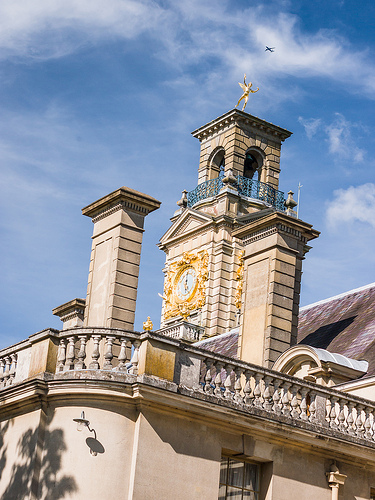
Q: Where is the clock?
A: On the tower.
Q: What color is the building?
A: Light brown.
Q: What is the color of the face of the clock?
A: White.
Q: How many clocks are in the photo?
A: 1.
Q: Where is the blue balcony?
A: At the top level of the tower.